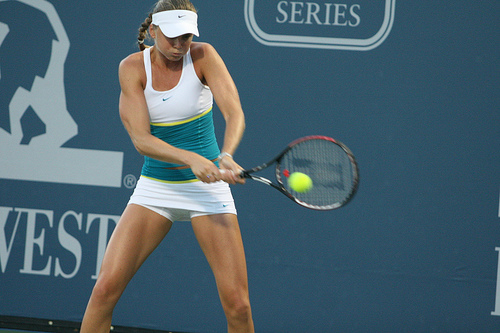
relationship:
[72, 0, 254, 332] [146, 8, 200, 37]
woman wearing visor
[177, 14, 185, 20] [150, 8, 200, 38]
black swoosh sewn on visor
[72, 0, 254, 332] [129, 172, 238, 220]
woman wearing skirt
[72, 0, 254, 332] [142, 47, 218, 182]
woman wearing tank top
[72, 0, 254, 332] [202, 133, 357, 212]
woman holding tennis racket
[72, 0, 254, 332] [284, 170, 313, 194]
woman hitting tennis ball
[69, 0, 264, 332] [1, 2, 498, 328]
player behind blue wall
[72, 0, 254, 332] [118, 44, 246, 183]
woman has arms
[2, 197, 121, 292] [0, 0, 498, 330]
white writing on wall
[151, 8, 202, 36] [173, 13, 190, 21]
white visor with swoosh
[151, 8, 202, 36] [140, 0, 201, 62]
white visor on womans head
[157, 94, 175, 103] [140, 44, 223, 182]
green swoosh on a tank top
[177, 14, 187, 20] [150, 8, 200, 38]
black swoosh on visor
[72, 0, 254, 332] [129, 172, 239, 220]
woman wearing shorts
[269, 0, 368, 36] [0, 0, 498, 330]
white lettering on wall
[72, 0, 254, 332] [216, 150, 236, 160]
woman wearing bracelet/watch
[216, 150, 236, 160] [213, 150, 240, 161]
bracelet/watch on wrist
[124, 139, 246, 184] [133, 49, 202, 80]
woman wearing visor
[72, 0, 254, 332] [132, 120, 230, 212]
woman middle of shirt turquoise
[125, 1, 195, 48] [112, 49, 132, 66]
woman's hair in a braid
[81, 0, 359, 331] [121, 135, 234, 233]
she wearing outfit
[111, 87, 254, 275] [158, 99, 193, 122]
she wearing visor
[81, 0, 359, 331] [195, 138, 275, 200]
she playing hard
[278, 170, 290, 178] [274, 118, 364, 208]
red spot on ten racket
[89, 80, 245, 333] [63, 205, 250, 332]
tennis player muscular legs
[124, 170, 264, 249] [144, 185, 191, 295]
edge of white ten skirt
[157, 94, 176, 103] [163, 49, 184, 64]
green swoosh on  sun visor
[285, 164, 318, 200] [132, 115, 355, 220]
tennis ball being hit by player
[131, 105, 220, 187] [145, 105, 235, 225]
middle of shirt of dress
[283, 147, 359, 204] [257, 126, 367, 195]
clear strings in racket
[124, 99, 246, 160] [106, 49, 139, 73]
woman's blond pony tail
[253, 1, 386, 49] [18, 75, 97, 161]
white logo on wall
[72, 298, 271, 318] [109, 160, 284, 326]
knees on ten player